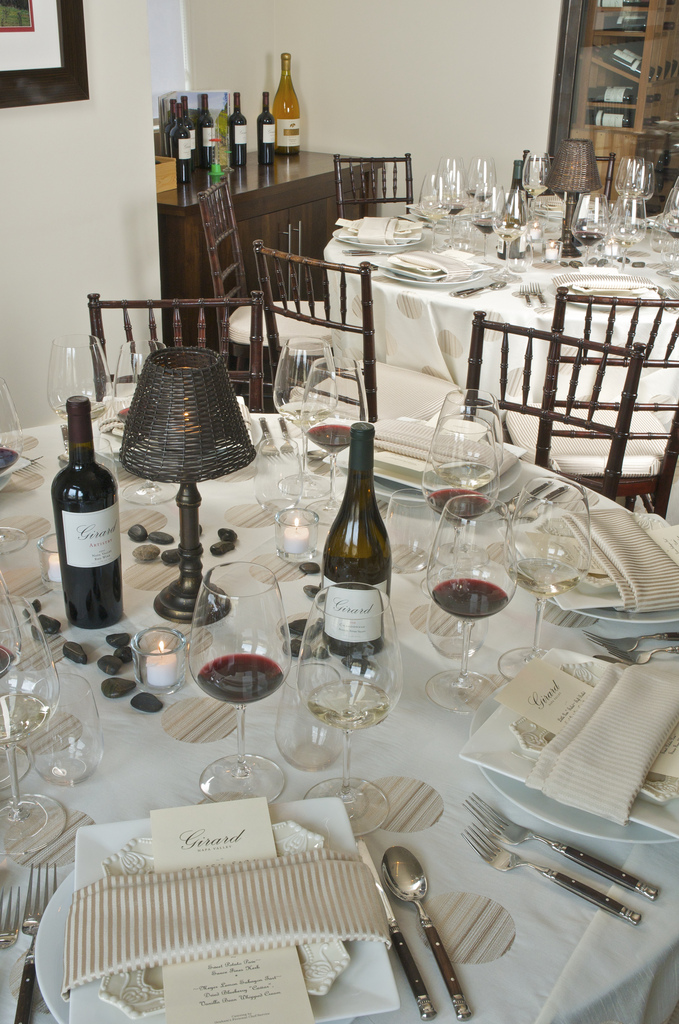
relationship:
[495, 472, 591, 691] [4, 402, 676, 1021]
glass on table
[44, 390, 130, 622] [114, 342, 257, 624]
bottle next to lamp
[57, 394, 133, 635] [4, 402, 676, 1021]
wine on table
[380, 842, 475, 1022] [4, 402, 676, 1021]
spoon on table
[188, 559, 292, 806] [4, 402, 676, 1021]
glass on table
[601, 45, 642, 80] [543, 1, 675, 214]
bottles on shelves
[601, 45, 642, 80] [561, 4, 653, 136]
bottles behind glass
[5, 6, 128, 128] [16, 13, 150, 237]
painting on wall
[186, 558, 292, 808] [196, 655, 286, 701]
glass has wine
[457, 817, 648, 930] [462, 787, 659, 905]
fork next to fork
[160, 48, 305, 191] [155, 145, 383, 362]
wine bottles on counter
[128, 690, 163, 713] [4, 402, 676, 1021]
rock on table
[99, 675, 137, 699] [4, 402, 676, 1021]
rock on table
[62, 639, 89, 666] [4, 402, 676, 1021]
rock on table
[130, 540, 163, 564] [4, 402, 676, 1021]
stone on table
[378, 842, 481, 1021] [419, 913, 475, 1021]
spoon has handle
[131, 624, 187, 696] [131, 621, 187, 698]
candle on holder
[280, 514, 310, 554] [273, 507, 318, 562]
candle on holder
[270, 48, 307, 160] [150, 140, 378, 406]
bottle on counter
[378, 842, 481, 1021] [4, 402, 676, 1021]
spoon sitting on top of table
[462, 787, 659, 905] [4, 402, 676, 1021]
fork sitting on table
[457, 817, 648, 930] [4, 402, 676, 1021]
fork sitting on table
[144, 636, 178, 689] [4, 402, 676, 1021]
candle sitting on table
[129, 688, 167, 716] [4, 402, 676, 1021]
rock sitting on table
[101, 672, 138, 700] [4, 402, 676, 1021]
rock sitting on table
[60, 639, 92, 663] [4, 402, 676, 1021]
rock sitting on table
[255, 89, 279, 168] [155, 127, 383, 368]
bottle on stand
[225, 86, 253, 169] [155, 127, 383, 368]
bottle on stand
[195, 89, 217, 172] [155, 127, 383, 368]
bottle on stand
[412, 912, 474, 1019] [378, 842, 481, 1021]
handle on spoon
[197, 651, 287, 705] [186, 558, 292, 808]
wine in glass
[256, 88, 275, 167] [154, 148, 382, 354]
bottle on table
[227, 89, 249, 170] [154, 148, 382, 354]
bottle on table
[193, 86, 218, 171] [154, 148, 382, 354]
bottle on table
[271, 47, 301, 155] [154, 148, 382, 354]
bottle on table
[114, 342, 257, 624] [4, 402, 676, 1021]
lamp on table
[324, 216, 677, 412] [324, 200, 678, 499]
tablecloth on table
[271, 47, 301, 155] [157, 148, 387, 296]
bottle on counter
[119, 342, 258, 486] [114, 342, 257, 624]
lampshade on lamp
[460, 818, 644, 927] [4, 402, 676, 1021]
fork on table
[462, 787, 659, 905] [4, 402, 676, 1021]
fork on table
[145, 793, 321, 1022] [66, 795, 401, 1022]
invitation on plate